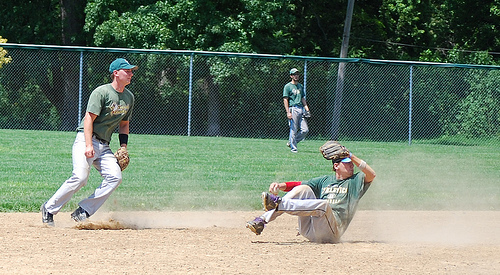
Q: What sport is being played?
A: Baseball.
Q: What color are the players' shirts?
A: Green.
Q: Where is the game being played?
A: Park.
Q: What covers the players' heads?
A: Caps.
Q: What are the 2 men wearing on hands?
A: Gloves.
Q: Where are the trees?
A: Outside the fence.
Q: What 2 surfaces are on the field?
A: Grass and dirt.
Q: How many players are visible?
A: 3.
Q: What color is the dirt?
A: Brown.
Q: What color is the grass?
A: Green.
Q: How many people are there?
A: Three.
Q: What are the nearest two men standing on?
A: Dirt.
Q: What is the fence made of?
A: Chain link.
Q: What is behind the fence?
A: Trees.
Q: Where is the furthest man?
A: On the grass.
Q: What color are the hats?
A: Blue.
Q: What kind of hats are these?
A: Baseball caps.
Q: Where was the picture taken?
A: A baseball park.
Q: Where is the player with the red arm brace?
A: Sitting on the ground, a few feet from the other player.